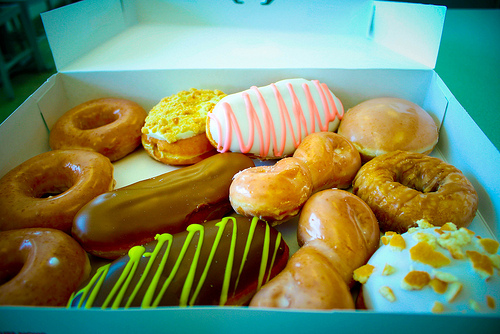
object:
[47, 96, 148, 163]
donuts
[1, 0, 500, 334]
box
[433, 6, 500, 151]
table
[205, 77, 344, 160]
donut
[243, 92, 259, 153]
glaze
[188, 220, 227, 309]
glaze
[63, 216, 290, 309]
donut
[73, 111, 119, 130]
hole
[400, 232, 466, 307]
topping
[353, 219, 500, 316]
donut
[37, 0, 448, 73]
lid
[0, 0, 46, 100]
cart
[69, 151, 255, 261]
donut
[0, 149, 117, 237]
donut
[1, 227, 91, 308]
donut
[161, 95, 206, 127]
topping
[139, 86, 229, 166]
donut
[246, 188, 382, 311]
donut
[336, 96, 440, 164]
donut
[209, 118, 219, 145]
frosting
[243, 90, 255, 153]
stripes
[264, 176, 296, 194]
sugar glaze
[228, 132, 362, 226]
donut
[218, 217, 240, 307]
stripes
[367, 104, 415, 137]
sugar glaze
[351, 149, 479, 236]
donut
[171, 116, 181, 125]
nuts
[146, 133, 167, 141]
glaze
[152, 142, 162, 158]
hole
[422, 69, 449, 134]
cardboard flap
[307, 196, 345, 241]
glaze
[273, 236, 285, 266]
chocolate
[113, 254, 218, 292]
topping